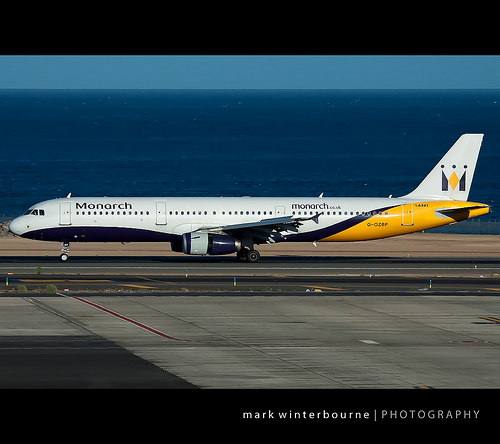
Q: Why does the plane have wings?
A: To keep the plane in the air.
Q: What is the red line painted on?
A: The runway.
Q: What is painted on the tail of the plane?
A: A logo.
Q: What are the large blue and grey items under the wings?
A: Engines.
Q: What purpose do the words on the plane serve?
A: To advertise the airline.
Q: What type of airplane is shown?
A: Passenger airplane.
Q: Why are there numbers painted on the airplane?
A: Identification.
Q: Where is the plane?
A: On the runway.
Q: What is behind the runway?
A: The water.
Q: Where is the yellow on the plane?
A: The back.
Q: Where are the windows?
A: On the plane.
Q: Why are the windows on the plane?
A: To see out of.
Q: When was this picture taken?
A: It was taken in the day time.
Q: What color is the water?
A: The water is blue.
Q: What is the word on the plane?
A: The word is monarch.